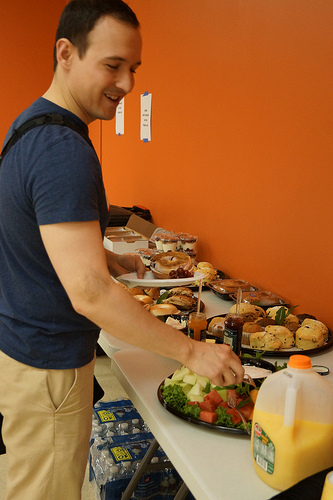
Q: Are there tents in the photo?
A: No, there are no tents.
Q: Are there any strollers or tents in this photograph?
A: No, there are no tents or strollers.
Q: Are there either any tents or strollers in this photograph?
A: No, there are no tents or strollers.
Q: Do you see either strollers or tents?
A: No, there are no tents or strollers.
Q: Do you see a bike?
A: No, there are no bikes.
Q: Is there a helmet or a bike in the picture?
A: No, there are no bikes or helmets.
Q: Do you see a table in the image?
A: Yes, there is a table.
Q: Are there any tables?
A: Yes, there is a table.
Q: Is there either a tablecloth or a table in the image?
A: Yes, there is a table.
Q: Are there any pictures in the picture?
A: No, there are no pictures.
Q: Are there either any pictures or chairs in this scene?
A: No, there are no pictures or chairs.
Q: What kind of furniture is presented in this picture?
A: The furniture is a table.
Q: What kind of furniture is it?
A: The piece of furniture is a table.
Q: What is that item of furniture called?
A: This is a table.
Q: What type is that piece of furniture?
A: This is a table.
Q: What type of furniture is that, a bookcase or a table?
A: This is a table.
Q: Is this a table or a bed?
A: This is a table.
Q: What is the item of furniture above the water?
A: The piece of furniture is a table.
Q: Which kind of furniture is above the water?
A: The piece of furniture is a table.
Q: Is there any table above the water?
A: Yes, there is a table above the water.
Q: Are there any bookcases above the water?
A: No, there is a table above the water.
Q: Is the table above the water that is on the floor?
A: Yes, the table is above the water.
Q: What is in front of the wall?
A: The table is in front of the wall.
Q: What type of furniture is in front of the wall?
A: The piece of furniture is a table.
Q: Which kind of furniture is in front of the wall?
A: The piece of furniture is a table.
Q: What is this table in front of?
A: The table is in front of the wall.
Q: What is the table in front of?
A: The table is in front of the wall.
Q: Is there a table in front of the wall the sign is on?
A: Yes, there is a table in front of the wall.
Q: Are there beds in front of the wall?
A: No, there is a table in front of the wall.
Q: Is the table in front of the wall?
A: Yes, the table is in front of the wall.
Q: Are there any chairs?
A: No, there are no chairs.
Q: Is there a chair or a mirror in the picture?
A: No, there are no chairs or mirrors.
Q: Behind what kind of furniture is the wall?
A: The wall is behind the table.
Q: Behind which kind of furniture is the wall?
A: The wall is behind the table.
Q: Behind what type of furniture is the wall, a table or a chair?
A: The wall is behind a table.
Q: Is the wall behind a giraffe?
A: No, the wall is behind the table.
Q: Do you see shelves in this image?
A: No, there are no shelves.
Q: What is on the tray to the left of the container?
A: The bagels are on the tray.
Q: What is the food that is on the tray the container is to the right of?
A: The food is bagels.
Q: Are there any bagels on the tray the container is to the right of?
A: Yes, there are bagels on the tray.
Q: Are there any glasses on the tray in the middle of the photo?
A: No, there are bagels on the tray.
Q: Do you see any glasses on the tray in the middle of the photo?
A: No, there are bagels on the tray.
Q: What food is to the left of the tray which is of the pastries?
A: The food is bagels.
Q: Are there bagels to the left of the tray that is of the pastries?
A: Yes, there are bagels to the left of the tray.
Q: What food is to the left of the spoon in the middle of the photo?
A: The food is bagels.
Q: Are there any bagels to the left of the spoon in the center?
A: Yes, there are bagels to the left of the spoon.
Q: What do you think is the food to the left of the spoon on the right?
A: The food is bagels.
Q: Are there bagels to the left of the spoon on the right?
A: Yes, there are bagels to the left of the spoon.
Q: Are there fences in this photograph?
A: No, there are no fences.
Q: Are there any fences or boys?
A: No, there are no fences or boys.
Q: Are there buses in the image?
A: No, there are no buses.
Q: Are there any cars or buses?
A: No, there are no buses or cars.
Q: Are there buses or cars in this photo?
A: No, there are no buses or cars.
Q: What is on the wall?
A: The sign is on the wall.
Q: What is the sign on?
A: The sign is on the wall.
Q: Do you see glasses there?
A: No, there are no glasses.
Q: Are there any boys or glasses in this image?
A: No, there are no glasses or boys.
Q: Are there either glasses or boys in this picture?
A: No, there are no glasses or boys.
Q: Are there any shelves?
A: No, there are no shelves.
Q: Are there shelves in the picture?
A: No, there are no shelves.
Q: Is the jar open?
A: Yes, the jar is open.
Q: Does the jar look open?
A: Yes, the jar is open.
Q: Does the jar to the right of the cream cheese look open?
A: Yes, the jar is open.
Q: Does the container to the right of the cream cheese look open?
A: Yes, the jar is open.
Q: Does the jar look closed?
A: No, the jar is open.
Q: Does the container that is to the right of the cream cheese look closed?
A: No, the jar is open.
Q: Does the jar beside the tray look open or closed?
A: The jar is open.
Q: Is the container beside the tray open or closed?
A: The jar is open.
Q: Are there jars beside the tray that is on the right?
A: Yes, there is a jar beside the tray.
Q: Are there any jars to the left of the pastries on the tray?
A: Yes, there is a jar to the left of the pastries.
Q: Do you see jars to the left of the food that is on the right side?
A: Yes, there is a jar to the left of the pastries.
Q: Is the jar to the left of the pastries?
A: Yes, the jar is to the left of the pastries.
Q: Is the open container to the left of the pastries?
A: Yes, the jar is to the left of the pastries.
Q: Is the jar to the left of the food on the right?
A: Yes, the jar is to the left of the pastries.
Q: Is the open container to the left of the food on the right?
A: Yes, the jar is to the left of the pastries.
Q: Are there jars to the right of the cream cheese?
A: Yes, there is a jar to the right of the cream cheese.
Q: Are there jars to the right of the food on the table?
A: Yes, there is a jar to the right of the cream cheese.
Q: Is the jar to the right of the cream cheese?
A: Yes, the jar is to the right of the cream cheese.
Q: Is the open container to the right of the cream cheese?
A: Yes, the jar is to the right of the cream cheese.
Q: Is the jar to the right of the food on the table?
A: Yes, the jar is to the right of the cream cheese.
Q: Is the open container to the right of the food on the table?
A: Yes, the jar is to the right of the cream cheese.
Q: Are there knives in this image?
A: No, there are no knives.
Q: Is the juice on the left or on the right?
A: The juice is on the right of the image.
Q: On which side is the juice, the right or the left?
A: The juice is on the right of the image.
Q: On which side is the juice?
A: The juice is on the right of the image.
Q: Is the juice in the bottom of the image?
A: Yes, the juice is in the bottom of the image.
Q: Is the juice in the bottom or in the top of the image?
A: The juice is in the bottom of the image.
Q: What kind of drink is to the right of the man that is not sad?
A: The drink is juice.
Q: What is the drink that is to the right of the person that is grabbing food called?
A: The drink is juice.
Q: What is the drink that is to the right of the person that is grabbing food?
A: The drink is juice.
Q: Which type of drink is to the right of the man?
A: The drink is juice.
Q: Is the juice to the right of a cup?
A: No, the juice is to the right of a man.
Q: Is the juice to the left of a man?
A: No, the juice is to the right of a man.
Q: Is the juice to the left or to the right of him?
A: The juice is to the right of the man.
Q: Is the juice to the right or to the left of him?
A: The juice is to the right of the man.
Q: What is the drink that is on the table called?
A: The drink is juice.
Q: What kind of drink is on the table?
A: The drink is juice.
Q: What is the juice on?
A: The juice is on the table.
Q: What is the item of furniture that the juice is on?
A: The piece of furniture is a table.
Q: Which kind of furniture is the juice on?
A: The juice is on the table.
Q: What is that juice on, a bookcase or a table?
A: The juice is on a table.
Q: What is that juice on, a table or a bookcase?
A: The juice is on a table.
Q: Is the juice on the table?
A: Yes, the juice is on the table.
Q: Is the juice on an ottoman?
A: No, the juice is on the table.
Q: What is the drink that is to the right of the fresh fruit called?
A: The drink is juice.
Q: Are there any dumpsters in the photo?
A: No, there are no dumpsters.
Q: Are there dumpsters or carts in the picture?
A: No, there are no dumpsters or carts.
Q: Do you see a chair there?
A: No, there are no chairs.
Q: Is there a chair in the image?
A: No, there are no chairs.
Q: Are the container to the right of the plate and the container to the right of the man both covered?
A: Yes, both the container and the container are covered.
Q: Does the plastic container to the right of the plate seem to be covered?
A: Yes, the container is covered.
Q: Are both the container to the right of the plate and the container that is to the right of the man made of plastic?
A: Yes, both the container and the container are made of plastic.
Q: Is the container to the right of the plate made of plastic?
A: Yes, the container is made of plastic.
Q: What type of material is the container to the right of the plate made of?
A: The container is made of plastic.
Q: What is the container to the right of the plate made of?
A: The container is made of plastic.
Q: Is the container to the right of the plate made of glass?
A: No, the container is made of plastic.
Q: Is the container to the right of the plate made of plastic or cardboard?
A: The container is made of plastic.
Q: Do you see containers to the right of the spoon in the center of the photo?
A: Yes, there is a container to the right of the spoon.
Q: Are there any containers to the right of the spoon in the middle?
A: Yes, there is a container to the right of the spoon.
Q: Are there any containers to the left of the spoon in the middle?
A: No, the container is to the right of the spoon.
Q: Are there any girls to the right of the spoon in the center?
A: No, there is a container to the right of the spoon.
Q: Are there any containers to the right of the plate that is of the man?
A: Yes, there is a container to the right of the plate.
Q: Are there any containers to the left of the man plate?
A: No, the container is to the right of the plate.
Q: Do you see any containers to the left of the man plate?
A: No, the container is to the right of the plate.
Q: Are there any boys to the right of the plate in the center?
A: No, there is a container to the right of the plate.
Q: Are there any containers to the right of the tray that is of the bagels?
A: Yes, there is a container to the right of the tray.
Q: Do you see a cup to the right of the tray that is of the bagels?
A: No, there is a container to the right of the tray.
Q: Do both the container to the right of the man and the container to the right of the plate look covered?
A: Yes, both the container and the container are covered.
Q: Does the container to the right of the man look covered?
A: Yes, the container is covered.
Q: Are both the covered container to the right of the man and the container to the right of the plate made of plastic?
A: Yes, both the container and the container are made of plastic.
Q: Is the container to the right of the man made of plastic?
A: Yes, the container is made of plastic.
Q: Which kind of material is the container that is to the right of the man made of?
A: The container is made of plastic.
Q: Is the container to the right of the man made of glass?
A: No, the container is made of plastic.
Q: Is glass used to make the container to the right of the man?
A: No, the container is made of plastic.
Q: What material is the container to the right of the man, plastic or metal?
A: The container is made of plastic.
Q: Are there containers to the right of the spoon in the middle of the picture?
A: Yes, there is a container to the right of the spoon.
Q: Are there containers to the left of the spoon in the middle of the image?
A: No, the container is to the right of the spoon.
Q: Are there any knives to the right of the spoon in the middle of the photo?
A: No, there is a container to the right of the spoon.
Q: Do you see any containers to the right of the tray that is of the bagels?
A: Yes, there is a container to the right of the tray.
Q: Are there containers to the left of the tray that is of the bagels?
A: No, the container is to the right of the tray.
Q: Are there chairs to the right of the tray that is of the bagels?
A: No, there is a container to the right of the tray.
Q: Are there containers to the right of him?
A: Yes, there is a container to the right of the man.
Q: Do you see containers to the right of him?
A: Yes, there is a container to the right of the man.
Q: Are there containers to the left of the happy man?
A: No, the container is to the right of the man.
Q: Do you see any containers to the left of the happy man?
A: No, the container is to the right of the man.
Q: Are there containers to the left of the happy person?
A: No, the container is to the right of the man.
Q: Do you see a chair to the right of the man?
A: No, there is a container to the right of the man.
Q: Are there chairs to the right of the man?
A: No, there is a container to the right of the man.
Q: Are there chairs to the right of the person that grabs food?
A: No, there is a container to the right of the man.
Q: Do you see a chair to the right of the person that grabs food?
A: No, there is a container to the right of the man.